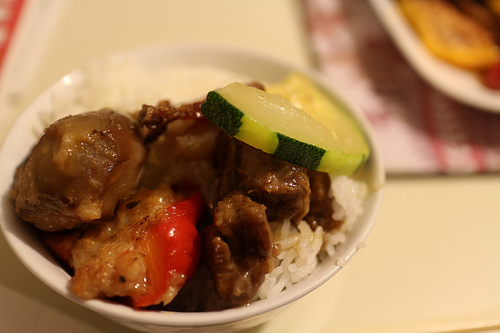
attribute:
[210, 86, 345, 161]
cucumber — green, round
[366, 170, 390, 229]
plate — white, round, close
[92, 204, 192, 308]
chicken — close, brown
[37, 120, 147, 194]
beef — black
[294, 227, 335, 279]
rice — white, small, ready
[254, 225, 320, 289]
rice grains — white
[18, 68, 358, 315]
meal — tasty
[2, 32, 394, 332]
plate — white